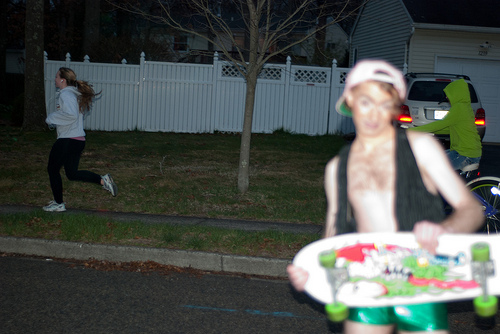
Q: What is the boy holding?
A: Skateboard.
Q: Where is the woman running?
A: Sidewalk.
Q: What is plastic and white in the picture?
A: Fence.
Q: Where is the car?
A: In a driveway.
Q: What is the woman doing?
A: Running.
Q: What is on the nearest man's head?
A: A hat.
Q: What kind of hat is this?
A: A baseball cap.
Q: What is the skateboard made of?
A: Wood.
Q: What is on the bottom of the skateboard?
A: Wheels.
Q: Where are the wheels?
A: On the bottom of the skateboard.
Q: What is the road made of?
A: Asphalt.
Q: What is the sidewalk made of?
A: Cement.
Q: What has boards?
A: The tall, white fence.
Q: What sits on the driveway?
A: A white SUV.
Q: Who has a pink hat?
A: A boy.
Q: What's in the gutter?
A: Brown leaves.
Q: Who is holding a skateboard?
A: Man with hairy chest, black vest and pink cap.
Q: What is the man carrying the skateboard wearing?
A: Black vest.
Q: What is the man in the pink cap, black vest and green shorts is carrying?
A: A skateboard.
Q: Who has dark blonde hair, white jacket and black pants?
A: The woman.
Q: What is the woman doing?
A: Jogging.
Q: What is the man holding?
A: Skateboard.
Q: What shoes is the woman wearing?
A: Running shoes.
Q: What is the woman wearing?
A: Jacket.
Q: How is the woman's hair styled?
A: Ponytail.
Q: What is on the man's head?
A: Hat.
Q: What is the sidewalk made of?
A: Concrete.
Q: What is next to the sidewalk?
A: Grass.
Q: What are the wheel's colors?
A: Green.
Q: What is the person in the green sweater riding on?
A: A bike.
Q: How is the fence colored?
A: White.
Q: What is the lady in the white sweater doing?
A: Running.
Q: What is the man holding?
A: Skate.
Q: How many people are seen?
A: 2.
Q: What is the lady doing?
A: Running.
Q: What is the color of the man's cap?
A: White.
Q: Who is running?
A: The lady.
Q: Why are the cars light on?
A: Parking lights.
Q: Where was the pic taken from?
A: Street.